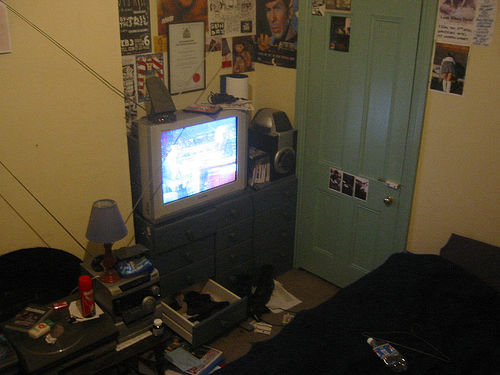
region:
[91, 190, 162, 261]
small lamp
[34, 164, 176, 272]
small lamp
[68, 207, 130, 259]
small lamp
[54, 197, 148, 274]
small lamp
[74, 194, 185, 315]
small lamp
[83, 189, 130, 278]
purple shade on lamp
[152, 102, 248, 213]
glow of television screen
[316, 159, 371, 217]
papers on green wood door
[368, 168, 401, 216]
lock and knob on door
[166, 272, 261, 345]
open drawer of bureau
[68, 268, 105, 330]
can with red cap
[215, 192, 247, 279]
knobs on closed drawers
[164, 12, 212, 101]
framed document on wall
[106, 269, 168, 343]
stereo with round knobs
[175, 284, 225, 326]
clothes in open drawer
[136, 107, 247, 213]
the silver tv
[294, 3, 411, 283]
the blue door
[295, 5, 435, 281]
the closed blue door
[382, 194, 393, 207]
the door knob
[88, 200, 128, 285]
the small lamp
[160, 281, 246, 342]
the opened drawer from the dresser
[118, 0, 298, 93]
the pictures on the wall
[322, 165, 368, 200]
the pictures near the door knob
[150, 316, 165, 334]
the small bottle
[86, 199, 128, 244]
the blue lamp shade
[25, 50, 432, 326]
A small messy bedroom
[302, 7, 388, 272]
A pale blue door with images tacked on it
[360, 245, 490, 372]
Bed with a dark blanket on top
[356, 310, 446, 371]
Empty soda bottle and wire hanger on bed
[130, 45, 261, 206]
Analog TV with rabbit ears is turned on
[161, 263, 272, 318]
Bottom drawer of dresser is open, exposing its contents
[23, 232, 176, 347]
Stereo and audio visual equipment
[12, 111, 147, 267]
Rabbit ears for the TV behind the lamp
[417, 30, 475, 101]
Picture of a girl in a school girl uniform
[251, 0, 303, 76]
A poster of Spock from the older version of the TV show Star Trek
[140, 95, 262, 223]
TV sitting on a chest of drawers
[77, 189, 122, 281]
Small table lamp sitting on an entertainment center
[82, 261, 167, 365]
Entertainment center or sitting on the floor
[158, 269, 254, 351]
Drawer pulled out of a chest of drawers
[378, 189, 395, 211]
Doorknob on the door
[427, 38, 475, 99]
Picture on the wall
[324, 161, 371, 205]
Pictures on the door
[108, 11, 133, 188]
Corner of a wall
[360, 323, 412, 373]
Water bottle sitting on a bed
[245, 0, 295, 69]
Movie poster attached to wall